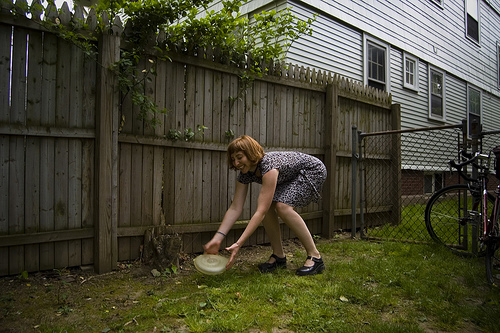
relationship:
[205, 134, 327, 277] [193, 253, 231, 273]
woman catching frisbee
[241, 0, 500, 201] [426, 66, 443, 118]
house has window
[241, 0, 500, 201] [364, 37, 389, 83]
house has window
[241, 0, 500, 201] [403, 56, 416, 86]
house has window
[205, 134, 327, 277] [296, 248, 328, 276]
woman has left foot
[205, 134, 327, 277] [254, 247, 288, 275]
woman has right foot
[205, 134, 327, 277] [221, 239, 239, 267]
woman has left hand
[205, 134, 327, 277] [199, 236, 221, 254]
woman has right hand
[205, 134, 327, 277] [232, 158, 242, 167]
woman has nose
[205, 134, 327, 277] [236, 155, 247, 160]
woman has left eye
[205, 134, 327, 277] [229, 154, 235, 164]
woman has right eye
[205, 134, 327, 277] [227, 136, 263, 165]
woman has hair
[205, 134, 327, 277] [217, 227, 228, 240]
woman has bracelet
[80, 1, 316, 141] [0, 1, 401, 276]
tree growing over fence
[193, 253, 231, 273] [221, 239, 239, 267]
frisbee in left hand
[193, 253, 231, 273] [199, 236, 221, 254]
frisbee in right hand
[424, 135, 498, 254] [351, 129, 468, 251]
bicycle leaning against gate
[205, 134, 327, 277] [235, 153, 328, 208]
woman wearing dress